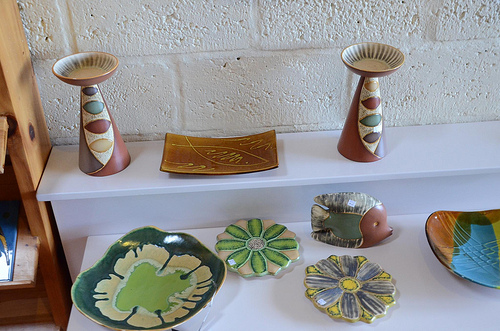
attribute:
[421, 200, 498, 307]
plate — craft, yellow, blue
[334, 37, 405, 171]
statue — oval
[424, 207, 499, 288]
bowl — colorful, craft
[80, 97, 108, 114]
design — oval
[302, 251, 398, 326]
pottery — yellow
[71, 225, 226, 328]
bowl — green, craft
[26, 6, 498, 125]
wall — concrete, white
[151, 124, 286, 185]
pottery — small, brown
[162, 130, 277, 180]
craft dish — brown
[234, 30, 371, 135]
brick — white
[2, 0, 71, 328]
book shelf — wooden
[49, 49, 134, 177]
candlestick holder — colorful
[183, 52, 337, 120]
brick — white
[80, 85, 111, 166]
design — oval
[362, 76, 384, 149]
design — oval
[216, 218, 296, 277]
flower — green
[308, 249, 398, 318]
flower — blue